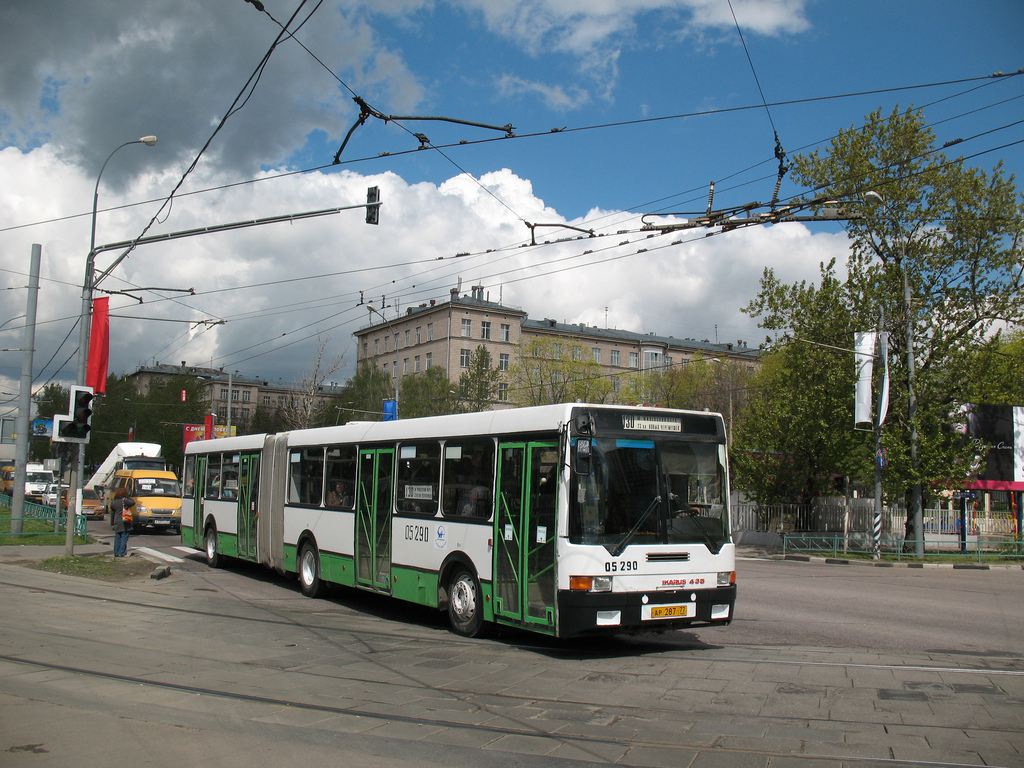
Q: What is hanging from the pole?
A: A red flag.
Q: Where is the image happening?
A: Near bus.